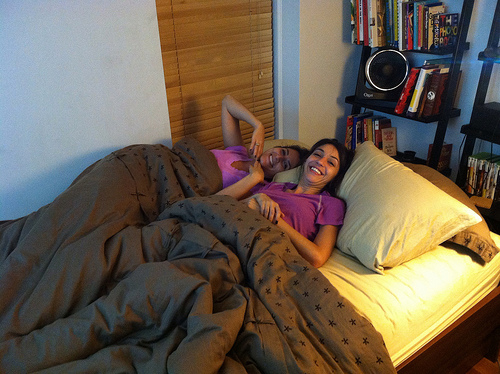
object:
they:
[208, 95, 357, 268]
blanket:
[0, 135, 394, 374]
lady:
[238, 137, 355, 268]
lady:
[208, 95, 311, 201]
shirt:
[209, 146, 272, 195]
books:
[349, 0, 459, 51]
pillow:
[397, 162, 499, 264]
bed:
[0, 136, 499, 373]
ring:
[255, 143, 259, 146]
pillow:
[334, 141, 482, 276]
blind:
[155, 0, 274, 150]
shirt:
[254, 182, 346, 241]